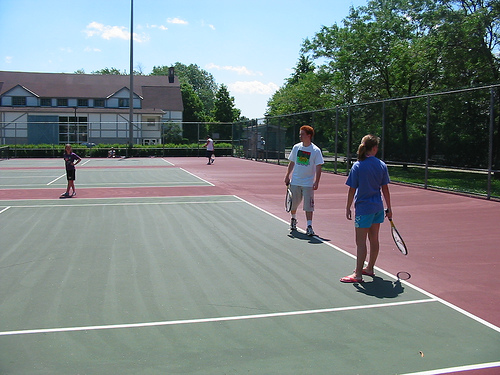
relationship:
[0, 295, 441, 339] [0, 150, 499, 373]
line on court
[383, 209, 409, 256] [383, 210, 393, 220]
racket in hand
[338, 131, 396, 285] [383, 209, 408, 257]
female holding racket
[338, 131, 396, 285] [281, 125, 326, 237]
female next to person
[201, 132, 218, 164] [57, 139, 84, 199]
person behind person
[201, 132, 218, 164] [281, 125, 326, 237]
person behind person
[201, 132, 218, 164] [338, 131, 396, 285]
person behind female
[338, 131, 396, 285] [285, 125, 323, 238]
female next to person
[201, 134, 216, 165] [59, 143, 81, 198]
person behind person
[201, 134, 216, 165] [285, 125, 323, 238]
person behind person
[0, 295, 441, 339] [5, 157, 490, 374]
line on court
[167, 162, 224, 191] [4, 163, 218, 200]
line on court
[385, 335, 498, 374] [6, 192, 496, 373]
line on court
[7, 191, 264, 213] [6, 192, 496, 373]
line on court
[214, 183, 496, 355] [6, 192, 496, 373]
line on court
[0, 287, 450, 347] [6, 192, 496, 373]
line on court